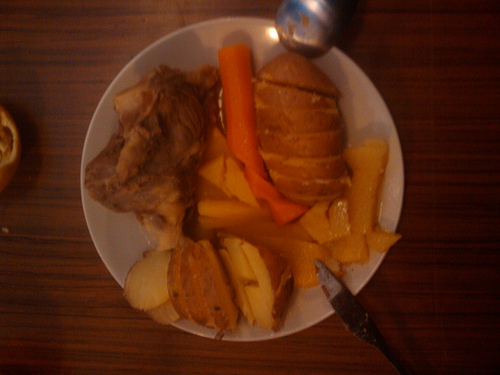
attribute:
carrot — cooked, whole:
[218, 42, 307, 225]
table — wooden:
[404, 66, 459, 184]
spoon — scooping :
[238, 1, 398, 78]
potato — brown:
[250, 43, 350, 213]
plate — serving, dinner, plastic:
[70, 11, 410, 348]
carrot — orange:
[219, 47, 299, 225]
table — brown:
[3, 4, 499, 374]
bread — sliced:
[221, 38, 390, 218]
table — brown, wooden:
[378, 10, 498, 351]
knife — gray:
[302, 254, 389, 356]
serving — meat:
[83, 60, 223, 252]